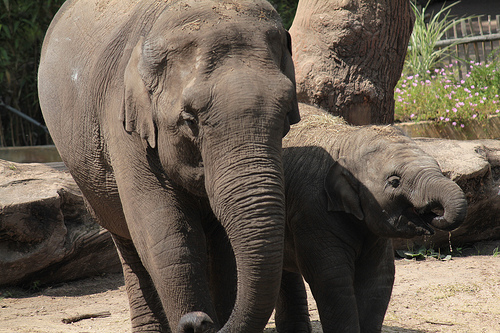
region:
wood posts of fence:
[411, 14, 497, 76]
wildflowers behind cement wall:
[403, 63, 498, 137]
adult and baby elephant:
[37, 0, 468, 332]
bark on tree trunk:
[288, 0, 413, 120]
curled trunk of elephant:
[401, 175, 466, 237]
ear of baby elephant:
[324, 155, 361, 220]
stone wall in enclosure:
[2, 136, 498, 293]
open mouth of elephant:
[400, 197, 445, 236]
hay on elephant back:
[288, 106, 403, 150]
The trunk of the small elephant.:
[423, 173, 468, 233]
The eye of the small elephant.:
[386, 168, 404, 192]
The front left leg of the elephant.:
[313, 247, 357, 331]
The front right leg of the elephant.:
[357, 243, 398, 331]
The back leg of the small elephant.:
[277, 264, 309, 328]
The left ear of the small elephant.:
[327, 161, 364, 225]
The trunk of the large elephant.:
[190, 155, 282, 327]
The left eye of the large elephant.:
[179, 111, 196, 132]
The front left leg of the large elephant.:
[129, 177, 220, 331]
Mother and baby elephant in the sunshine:
[36, 0, 467, 332]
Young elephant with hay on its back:
[268, 98, 470, 330]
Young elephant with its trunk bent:
[256, 100, 473, 332]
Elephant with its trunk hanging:
[32, 9, 302, 328]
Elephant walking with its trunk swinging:
[33, 10, 304, 329]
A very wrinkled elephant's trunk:
[203, 63, 285, 331]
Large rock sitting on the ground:
[0, 158, 122, 299]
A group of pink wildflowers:
[393, 64, 498, 128]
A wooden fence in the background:
[393, 11, 498, 94]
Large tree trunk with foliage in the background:
[301, 9, 448, 97]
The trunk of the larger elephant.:
[207, 147, 292, 331]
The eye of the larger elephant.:
[180, 111, 197, 132]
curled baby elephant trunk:
[404, 160, 474, 237]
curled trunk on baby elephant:
[408, 167, 469, 241]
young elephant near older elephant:
[247, 112, 468, 331]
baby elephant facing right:
[271, 125, 470, 330]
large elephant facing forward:
[21, 0, 311, 329]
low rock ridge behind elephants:
[2, 137, 498, 285]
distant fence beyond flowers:
[408, 6, 498, 84]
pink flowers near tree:
[390, 55, 499, 130]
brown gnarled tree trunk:
[282, 0, 419, 127]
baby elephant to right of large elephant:
[267, 123, 468, 331]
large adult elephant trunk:
[161, 117, 301, 332]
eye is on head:
[176, 107, 201, 132]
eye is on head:
[282, 109, 297, 126]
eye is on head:
[383, 173, 401, 189]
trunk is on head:
[403, 169, 468, 231]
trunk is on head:
[172, 91, 284, 331]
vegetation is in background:
[394, 0, 499, 140]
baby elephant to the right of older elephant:
[257, 118, 464, 331]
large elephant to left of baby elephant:
[36, 0, 301, 329]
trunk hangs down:
[179, 107, 286, 332]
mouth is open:
[397, 208, 436, 240]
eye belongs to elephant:
[178, 111, 203, 133]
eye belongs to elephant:
[282, 110, 294, 125]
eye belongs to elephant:
[385, 175, 403, 190]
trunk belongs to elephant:
[177, 110, 286, 330]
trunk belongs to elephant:
[403, 165, 469, 232]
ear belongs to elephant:
[119, 37, 161, 150]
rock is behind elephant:
[2, 156, 126, 292]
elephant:
[296, 95, 468, 330]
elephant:
[23, 0, 303, 317]